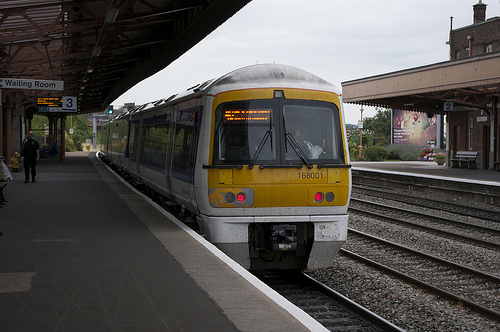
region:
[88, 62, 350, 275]
white and yellow train on tracks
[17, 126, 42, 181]
person standing next to the train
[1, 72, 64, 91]
blue letters on a white sign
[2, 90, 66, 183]
white sign above man in black shirt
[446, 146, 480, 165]
wooden bench next to train station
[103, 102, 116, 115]
green light hanging above train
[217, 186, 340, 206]
two red headlights on train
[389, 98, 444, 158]
purple poster next to train station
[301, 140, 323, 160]
white bag inside of train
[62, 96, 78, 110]
white sign hanging from the roof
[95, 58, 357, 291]
white train with yellow front on train tracks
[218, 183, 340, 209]
two red headlights on front of train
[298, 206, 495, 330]
three sets of train tracks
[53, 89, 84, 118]
balck and white numbered sign hanging from train platform ceiling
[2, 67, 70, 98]
waiting room sign on train platform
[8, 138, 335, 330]
long grey train platform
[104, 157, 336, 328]
white painted curb of train platform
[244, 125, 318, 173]
two windshield wipers on train windshield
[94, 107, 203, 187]
windows on side of train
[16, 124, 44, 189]
person standing on train platform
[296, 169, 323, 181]
Black numbers on train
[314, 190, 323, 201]
Pink headlight on train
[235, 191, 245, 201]
Pink headlight on train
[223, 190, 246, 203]
Round headlights on train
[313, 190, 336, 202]
Round headlights on train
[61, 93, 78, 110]
Black and white sign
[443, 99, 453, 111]
Black and white sign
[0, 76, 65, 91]
Black and white sign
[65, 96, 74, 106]
Black number on sign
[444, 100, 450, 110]
Black number on sign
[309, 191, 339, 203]
two red circular lights on the front of a train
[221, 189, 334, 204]
four lights on the front of a train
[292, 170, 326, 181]
number print on the front of a train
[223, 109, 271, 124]
orange sign reflected on the front of a train's windshield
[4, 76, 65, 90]
white sign reading waiting room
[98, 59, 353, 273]
yellow and white train on a track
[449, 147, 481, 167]
bench on a train platform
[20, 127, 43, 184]
man standing on a train platform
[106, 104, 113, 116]
green go signal light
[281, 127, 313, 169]
windshield wiper on a train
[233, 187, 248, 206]
Red light on front right of train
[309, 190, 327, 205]
Red light on front left of train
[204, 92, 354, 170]
Front windshield of train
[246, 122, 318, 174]
Windshield wipers on a train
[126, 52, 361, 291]
Yellow train stopped at a station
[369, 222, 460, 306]
Metal and wood train tracks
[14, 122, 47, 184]
A man standing on a train platform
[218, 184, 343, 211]
Front headlights on a yellow train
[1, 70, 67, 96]
Waiting room sign at train station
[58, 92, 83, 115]
Number 3 sign at train station